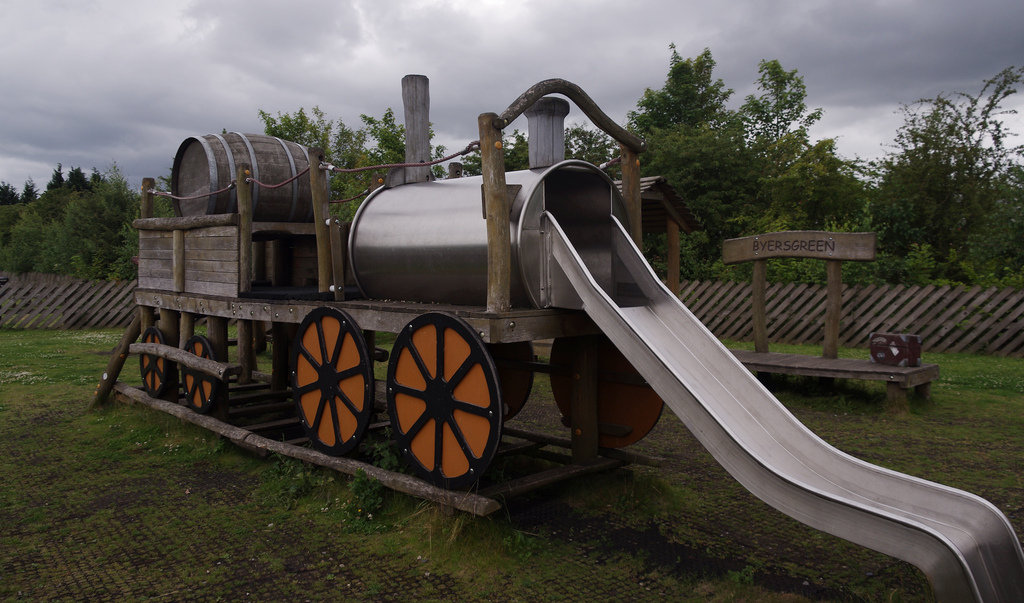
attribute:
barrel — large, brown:
[168, 130, 320, 208]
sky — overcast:
[4, 7, 975, 186]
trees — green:
[626, 37, 1012, 278]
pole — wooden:
[468, 119, 516, 322]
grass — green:
[55, 441, 385, 598]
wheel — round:
[396, 315, 504, 497]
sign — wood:
[720, 224, 883, 268]